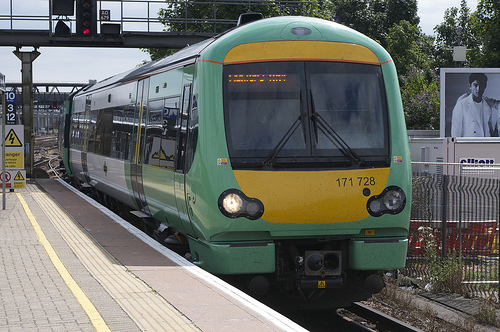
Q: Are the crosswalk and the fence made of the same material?
A: Yes, both the crosswalk and the fence are made of metal.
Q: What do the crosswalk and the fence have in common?
A: The material, both the crosswalk and the fence are metallic.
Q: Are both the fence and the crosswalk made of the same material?
A: Yes, both the fence and the crosswalk are made of metal.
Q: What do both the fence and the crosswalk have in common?
A: The material, both the fence and the crosswalk are metallic.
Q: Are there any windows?
A: Yes, there are windows.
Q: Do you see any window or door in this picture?
A: Yes, there are windows.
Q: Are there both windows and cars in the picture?
A: No, there are windows but no cars.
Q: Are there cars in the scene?
A: No, there are no cars.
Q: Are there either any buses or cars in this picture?
A: No, there are no cars or buses.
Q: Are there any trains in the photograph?
A: Yes, there is a train.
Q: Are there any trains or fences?
A: Yes, there is a train.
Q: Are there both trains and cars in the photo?
A: No, there is a train but no cars.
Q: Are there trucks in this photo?
A: No, there are no trucks.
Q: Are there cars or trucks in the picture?
A: No, there are no trucks or cars.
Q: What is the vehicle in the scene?
A: The vehicle is a train.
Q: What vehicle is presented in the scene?
A: The vehicle is a train.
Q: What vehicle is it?
A: The vehicle is a train.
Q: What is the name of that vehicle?
A: This is a train.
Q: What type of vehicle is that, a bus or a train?
A: This is a train.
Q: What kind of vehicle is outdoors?
A: The vehicle is a train.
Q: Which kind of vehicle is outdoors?
A: The vehicle is a train.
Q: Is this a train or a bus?
A: This is a train.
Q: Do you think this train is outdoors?
A: Yes, the train is outdoors.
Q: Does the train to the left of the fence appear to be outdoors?
A: Yes, the train is outdoors.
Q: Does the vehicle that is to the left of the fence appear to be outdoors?
A: Yes, the train is outdoors.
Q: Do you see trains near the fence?
A: Yes, there is a train near the fence.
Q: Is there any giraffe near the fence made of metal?
A: No, there is a train near the fence.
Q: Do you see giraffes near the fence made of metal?
A: No, there is a train near the fence.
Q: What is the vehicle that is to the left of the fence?
A: The vehicle is a train.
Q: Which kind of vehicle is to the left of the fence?
A: The vehicle is a train.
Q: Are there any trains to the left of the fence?
A: Yes, there is a train to the left of the fence.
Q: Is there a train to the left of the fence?
A: Yes, there is a train to the left of the fence.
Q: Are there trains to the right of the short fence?
A: No, the train is to the left of the fence.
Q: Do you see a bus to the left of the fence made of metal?
A: No, there is a train to the left of the fence.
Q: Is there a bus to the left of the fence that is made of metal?
A: No, there is a train to the left of the fence.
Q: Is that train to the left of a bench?
A: No, the train is to the left of the fence.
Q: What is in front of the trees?
A: The train is in front of the trees.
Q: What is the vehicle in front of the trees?
A: The vehicle is a train.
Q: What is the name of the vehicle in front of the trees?
A: The vehicle is a train.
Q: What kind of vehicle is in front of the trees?
A: The vehicle is a train.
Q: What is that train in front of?
A: The train is in front of the trees.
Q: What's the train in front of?
A: The train is in front of the trees.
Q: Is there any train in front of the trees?
A: Yes, there is a train in front of the trees.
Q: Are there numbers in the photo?
A: Yes, there are numbers.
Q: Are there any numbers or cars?
A: Yes, there are numbers.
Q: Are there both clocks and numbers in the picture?
A: No, there are numbers but no clocks.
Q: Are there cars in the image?
A: No, there are no cars.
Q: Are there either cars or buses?
A: No, there are no cars or buses.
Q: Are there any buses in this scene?
A: No, there are no buses.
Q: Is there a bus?
A: No, there are no buses.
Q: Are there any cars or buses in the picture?
A: No, there are no buses or cars.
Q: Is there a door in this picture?
A: Yes, there is a door.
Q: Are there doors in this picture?
A: Yes, there is a door.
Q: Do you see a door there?
A: Yes, there is a door.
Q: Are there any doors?
A: Yes, there is a door.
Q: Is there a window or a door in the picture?
A: Yes, there is a door.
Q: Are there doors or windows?
A: Yes, there is a door.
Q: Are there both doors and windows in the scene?
A: Yes, there are both a door and windows.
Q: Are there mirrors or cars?
A: No, there are no cars or mirrors.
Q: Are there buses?
A: No, there are no buses.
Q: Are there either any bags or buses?
A: No, there are no buses or bags.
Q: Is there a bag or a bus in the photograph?
A: No, there are no buses or bags.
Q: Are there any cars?
A: No, there are no cars.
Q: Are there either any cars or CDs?
A: No, there are no cars or cds.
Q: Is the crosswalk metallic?
A: Yes, the crosswalk is metallic.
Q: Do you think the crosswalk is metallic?
A: Yes, the crosswalk is metallic.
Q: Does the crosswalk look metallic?
A: Yes, the crosswalk is metallic.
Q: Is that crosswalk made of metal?
A: Yes, the crosswalk is made of metal.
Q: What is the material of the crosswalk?
A: The crosswalk is made of metal.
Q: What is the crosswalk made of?
A: The crosswalk is made of metal.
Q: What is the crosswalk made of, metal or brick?
A: The crosswalk is made of metal.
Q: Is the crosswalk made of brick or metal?
A: The crosswalk is made of metal.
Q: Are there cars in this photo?
A: No, there are no cars.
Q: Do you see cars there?
A: No, there are no cars.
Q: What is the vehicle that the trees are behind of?
A: The vehicle is a train.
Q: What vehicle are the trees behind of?
A: The trees are behind the train.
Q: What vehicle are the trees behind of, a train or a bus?
A: The trees are behind a train.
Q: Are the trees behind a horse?
A: No, the trees are behind a train.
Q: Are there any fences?
A: Yes, there is a fence.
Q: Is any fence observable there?
A: Yes, there is a fence.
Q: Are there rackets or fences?
A: Yes, there is a fence.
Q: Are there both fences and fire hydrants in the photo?
A: No, there is a fence but no fire hydrants.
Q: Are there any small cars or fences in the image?
A: Yes, there is a small fence.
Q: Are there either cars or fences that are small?
A: Yes, the fence is small.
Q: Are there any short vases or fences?
A: Yes, there is a short fence.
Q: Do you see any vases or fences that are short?
A: Yes, the fence is short.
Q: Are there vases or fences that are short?
A: Yes, the fence is short.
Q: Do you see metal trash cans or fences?
A: Yes, there is a metal fence.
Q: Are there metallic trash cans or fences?
A: Yes, there is a metal fence.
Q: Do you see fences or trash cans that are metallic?
A: Yes, the fence is metallic.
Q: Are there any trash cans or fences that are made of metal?
A: Yes, the fence is made of metal.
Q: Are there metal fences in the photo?
A: Yes, there is a metal fence.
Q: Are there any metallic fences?
A: Yes, there is a metal fence.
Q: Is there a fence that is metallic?
A: Yes, there is a fence that is metallic.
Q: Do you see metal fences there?
A: Yes, there is a fence that is made of metal.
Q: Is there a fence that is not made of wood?
A: Yes, there is a fence that is made of metal.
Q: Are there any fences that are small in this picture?
A: Yes, there is a small fence.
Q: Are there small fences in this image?
A: Yes, there is a small fence.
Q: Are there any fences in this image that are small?
A: Yes, there is a fence that is small.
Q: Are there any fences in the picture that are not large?
A: Yes, there is a small fence.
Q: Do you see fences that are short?
A: Yes, there is a short fence.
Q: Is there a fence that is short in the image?
A: Yes, there is a short fence.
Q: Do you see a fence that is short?
A: Yes, there is a fence that is short.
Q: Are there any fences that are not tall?
A: Yes, there is a short fence.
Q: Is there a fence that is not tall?
A: Yes, there is a short fence.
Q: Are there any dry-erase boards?
A: No, there are no dry-erase boards.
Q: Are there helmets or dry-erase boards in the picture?
A: No, there are no dry-erase boards or helmets.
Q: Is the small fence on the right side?
A: Yes, the fence is on the right of the image.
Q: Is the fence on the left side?
A: No, the fence is on the right of the image.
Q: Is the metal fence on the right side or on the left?
A: The fence is on the right of the image.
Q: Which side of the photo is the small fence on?
A: The fence is on the right of the image.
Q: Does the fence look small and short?
A: Yes, the fence is small and short.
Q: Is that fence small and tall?
A: No, the fence is small but short.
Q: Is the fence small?
A: Yes, the fence is small.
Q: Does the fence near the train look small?
A: Yes, the fence is small.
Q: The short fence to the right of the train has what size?
A: The fence is small.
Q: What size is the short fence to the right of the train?
A: The fence is small.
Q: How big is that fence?
A: The fence is small.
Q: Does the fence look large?
A: No, the fence is small.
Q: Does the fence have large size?
A: No, the fence is small.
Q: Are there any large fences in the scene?
A: No, there is a fence but it is small.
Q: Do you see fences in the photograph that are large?
A: No, there is a fence but it is small.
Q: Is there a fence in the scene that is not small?
A: No, there is a fence but it is small.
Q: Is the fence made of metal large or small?
A: The fence is small.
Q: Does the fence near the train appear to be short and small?
A: Yes, the fence is short and small.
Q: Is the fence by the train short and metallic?
A: Yes, the fence is short and metallic.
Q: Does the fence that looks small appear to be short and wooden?
A: No, the fence is short but metallic.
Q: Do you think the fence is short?
A: Yes, the fence is short.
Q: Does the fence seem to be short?
A: Yes, the fence is short.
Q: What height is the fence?
A: The fence is short.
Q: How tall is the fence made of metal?
A: The fence is short.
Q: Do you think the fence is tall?
A: No, the fence is short.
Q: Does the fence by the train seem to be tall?
A: No, the fence is short.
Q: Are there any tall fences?
A: No, there is a fence but it is short.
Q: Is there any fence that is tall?
A: No, there is a fence but it is short.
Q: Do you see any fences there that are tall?
A: No, there is a fence but it is short.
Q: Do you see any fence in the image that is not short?
A: No, there is a fence but it is short.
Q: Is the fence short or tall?
A: The fence is short.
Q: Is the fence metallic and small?
A: Yes, the fence is metallic and small.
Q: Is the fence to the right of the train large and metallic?
A: No, the fence is metallic but small.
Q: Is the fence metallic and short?
A: Yes, the fence is metallic and short.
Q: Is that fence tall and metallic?
A: No, the fence is metallic but short.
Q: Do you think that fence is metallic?
A: Yes, the fence is metallic.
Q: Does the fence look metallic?
A: Yes, the fence is metallic.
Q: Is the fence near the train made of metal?
A: Yes, the fence is made of metal.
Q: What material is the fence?
A: The fence is made of metal.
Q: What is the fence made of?
A: The fence is made of metal.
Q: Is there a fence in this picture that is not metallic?
A: No, there is a fence but it is metallic.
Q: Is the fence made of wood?
A: No, the fence is made of metal.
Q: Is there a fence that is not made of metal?
A: No, there is a fence but it is made of metal.